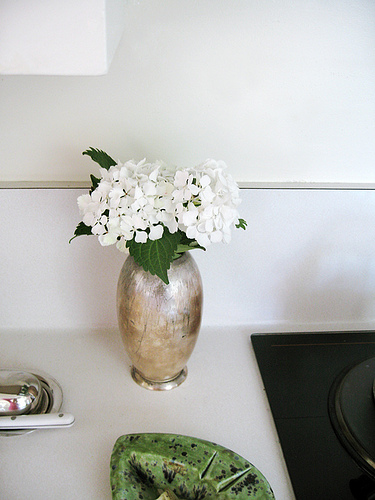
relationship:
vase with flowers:
[116, 252, 204, 387] [76, 160, 239, 255]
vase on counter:
[116, 252, 204, 387] [3, 328, 375, 498]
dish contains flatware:
[1, 370, 74, 433] [3, 414, 79, 428]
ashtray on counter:
[109, 432, 269, 495] [3, 328, 375, 498]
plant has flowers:
[72, 146, 251, 283] [76, 160, 239, 255]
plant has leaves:
[72, 146, 251, 283] [81, 143, 115, 191]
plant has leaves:
[72, 146, 251, 283] [127, 228, 200, 279]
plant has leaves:
[72, 146, 251, 283] [72, 222, 102, 243]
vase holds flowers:
[116, 252, 204, 387] [76, 160, 239, 255]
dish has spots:
[109, 432, 269, 495] [171, 442, 253, 493]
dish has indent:
[109, 432, 269, 495] [199, 451, 218, 476]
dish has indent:
[109, 432, 269, 495] [219, 463, 254, 490]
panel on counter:
[250, 324, 373, 495] [3, 328, 375, 498]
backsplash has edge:
[3, 179, 375, 326] [3, 180, 374, 193]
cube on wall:
[4, 3, 129, 77] [7, 4, 372, 192]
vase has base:
[116, 252, 204, 387] [128, 369, 193, 390]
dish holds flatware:
[1, 370, 74, 433] [3, 414, 79, 428]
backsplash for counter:
[3, 179, 375, 326] [3, 328, 375, 498]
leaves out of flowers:
[81, 143, 115, 191] [76, 160, 239, 255]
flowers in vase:
[76, 160, 239, 255] [116, 252, 204, 387]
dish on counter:
[109, 432, 269, 495] [3, 328, 375, 498]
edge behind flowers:
[3, 180, 374, 193] [76, 160, 239, 255]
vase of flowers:
[116, 252, 204, 387] [76, 160, 239, 255]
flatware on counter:
[3, 414, 79, 428] [3, 328, 375, 498]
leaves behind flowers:
[81, 143, 115, 191] [76, 160, 239, 255]